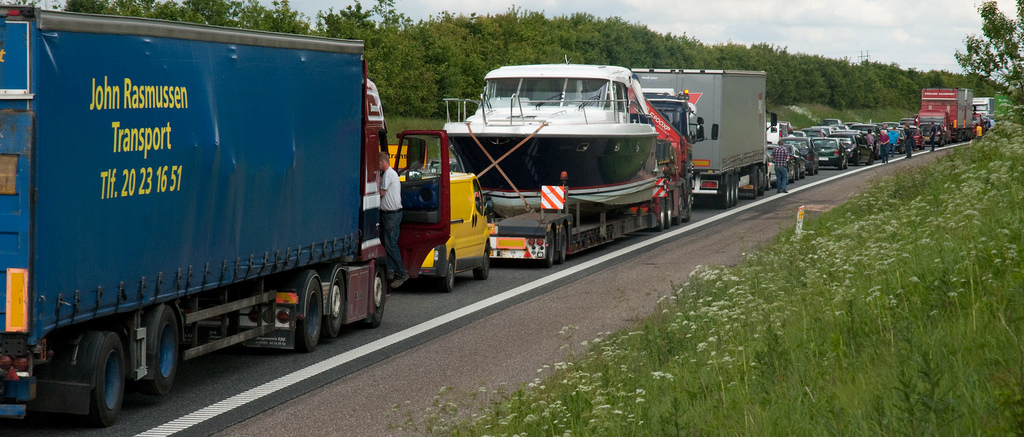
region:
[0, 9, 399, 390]
a blue semi truck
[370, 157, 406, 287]
a person in a white shirt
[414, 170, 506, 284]
a yellow van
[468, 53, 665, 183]
a boat on a trailer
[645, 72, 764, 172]
a silver truck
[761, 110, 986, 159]
cars on the street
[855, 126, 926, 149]
people standing on the side of the street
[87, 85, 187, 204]
writing on the truck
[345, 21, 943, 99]
trees by the road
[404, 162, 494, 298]
a car on a street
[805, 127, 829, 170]
a car on a street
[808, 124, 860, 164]
a car on a street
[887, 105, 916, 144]
a car on a street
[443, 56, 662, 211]
A boat on a trailer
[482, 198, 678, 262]
A low boy trailer on the road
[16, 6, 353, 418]
A blue trailer on the road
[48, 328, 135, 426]
Tires on a trailer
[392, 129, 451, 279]
The door on a truck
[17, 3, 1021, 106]
Green trees beside a road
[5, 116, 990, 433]
A road through the country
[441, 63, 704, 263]
boat on the back of a truck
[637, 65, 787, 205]
gray truck on the road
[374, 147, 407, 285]
person climbing into cab of truck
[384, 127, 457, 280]
door is open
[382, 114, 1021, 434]
wildflowers growing next to the shoulder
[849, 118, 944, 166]
people walking next to the road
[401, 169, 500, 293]
yellow vehicle behind the boat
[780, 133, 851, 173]
car in front of car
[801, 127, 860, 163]
a car on a street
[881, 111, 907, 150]
a car on a street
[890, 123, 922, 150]
a car on a street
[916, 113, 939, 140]
a car on a street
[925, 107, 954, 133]
a car on a street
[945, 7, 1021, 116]
a tree in a field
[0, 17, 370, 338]
blue transport bed with yellow letters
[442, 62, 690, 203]
large white boat transported on road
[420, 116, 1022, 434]
tall green grass on side of road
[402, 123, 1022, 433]
white flowers mixed with tall green grass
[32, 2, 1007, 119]
row of large trees with green leaves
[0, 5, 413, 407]
vehicle parked on the black street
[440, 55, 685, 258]
vehicle parked on the black street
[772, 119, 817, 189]
vehicle parked on the black street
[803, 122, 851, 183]
vehicle parked on the black street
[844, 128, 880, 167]
vehicle parked on the black street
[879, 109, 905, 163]
vehicle parked on the black street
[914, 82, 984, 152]
vehicle parked on the black street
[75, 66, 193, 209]
The yellow letters and numbers on the side of the truck.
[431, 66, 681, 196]
The boat being transported.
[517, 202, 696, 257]
The wheels under the transporting unit carrying the boat.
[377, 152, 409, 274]
The person standing in the open door of the blue truck.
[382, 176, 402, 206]
The white shirt the person is wearing at the door of the truck.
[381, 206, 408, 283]
The pants the person standing in the door of the truck is wearing.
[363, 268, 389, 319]
The front tire of the blue truck.